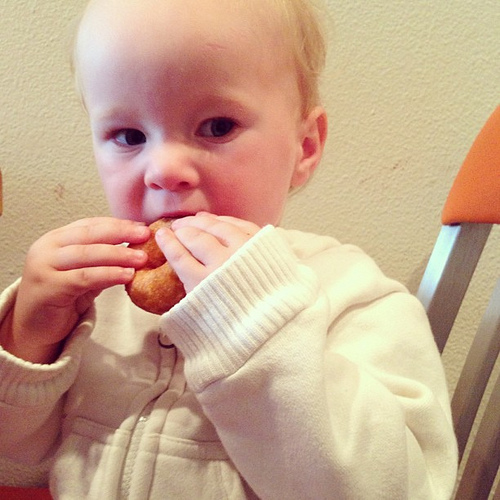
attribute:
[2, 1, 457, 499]
baby — blonde, bold, girl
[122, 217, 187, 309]
donut — brown, small, eaten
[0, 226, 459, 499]
sweater — white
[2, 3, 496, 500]
wall — tan, white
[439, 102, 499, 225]
stuff — orange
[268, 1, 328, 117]
hair — blonde, pale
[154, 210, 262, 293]
hand — small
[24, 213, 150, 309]
hand — small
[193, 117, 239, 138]
eye — brown, dark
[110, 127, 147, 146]
eye — brown, dark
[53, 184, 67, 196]
food — dark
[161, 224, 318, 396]
cuff — ribbed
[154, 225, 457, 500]
sleeve — ribbed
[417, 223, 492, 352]
bar — metal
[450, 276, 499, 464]
bar — metal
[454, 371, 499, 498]
bar — metal